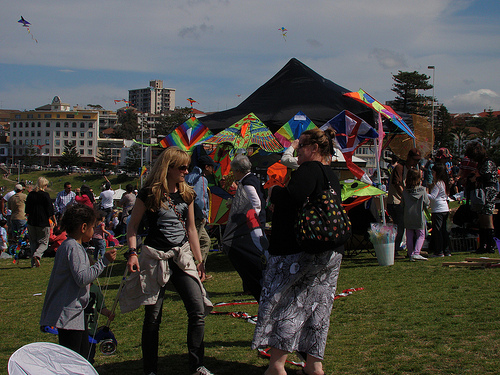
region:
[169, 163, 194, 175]
dark brown sunglasses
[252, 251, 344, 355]
a woman's long gray skirt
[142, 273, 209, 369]
a woman's pants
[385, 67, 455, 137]
part of a tall green tree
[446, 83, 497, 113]
a small white cloud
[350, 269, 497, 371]
a section of green grass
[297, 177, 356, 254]
a large multicolored purse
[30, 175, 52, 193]
a woman's blonde hair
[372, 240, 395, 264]
a large white bucket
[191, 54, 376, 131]
a large black tent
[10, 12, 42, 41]
Airplane kite flying in air.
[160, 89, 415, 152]
Group of colorful kites.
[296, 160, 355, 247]
Black polka-dot purse on woman's shoulder.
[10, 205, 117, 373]
Little girl holding white kite.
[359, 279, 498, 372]
Patchy green grass on ground.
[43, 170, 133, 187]
Shadows of trees on grass.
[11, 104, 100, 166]
White business building in background.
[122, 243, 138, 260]
Multiple bracelets on woman's wrist.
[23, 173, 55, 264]
Blond hair woman walking.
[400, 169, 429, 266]
Little girl wearing purple pants.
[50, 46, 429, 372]
people standing in a field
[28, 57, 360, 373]
people standing on the grass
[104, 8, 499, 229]
kites on a tent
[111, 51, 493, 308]
kites on a black tent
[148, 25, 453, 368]
a tent in a field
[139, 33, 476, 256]
a black tent in a field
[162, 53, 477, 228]
a tent with kites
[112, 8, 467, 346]
black tent with kites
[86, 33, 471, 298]
an area iwth people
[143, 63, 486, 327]
an area with kties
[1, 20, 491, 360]
The people are attending a festival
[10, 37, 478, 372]
Some people are at the county fair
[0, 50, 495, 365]
The people are all walking around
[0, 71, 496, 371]
The people are enjoying themselves greatly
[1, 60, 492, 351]
The people are with their children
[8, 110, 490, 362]
The people are walking in the grass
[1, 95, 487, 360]
The people are in a big park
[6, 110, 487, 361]
The people are on their day off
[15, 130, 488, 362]
The people are enjoying the day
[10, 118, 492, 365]
The people are enjoying the weather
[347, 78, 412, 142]
rainbow kite flying in sky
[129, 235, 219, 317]
jacket wrapped around waist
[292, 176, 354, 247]
multi colored polka dot purse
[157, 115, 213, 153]
rainbow kite in sky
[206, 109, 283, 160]
green and red kite in sky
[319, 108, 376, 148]
red white and blue kite in sky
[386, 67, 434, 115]
tree with green leaves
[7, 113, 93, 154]
multi story building with yellow top floor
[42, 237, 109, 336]
person wearing gray shirt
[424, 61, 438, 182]
metal lamp post in distance